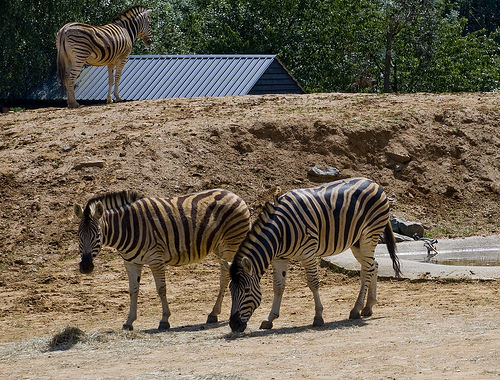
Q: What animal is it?
A: Zebra.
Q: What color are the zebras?
A: Black and white.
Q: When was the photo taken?
A: Daytime.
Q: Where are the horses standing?
A: On ground.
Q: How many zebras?
A: Three.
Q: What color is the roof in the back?
A: Blue.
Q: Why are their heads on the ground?
A: Eating.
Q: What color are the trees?
A: Green.